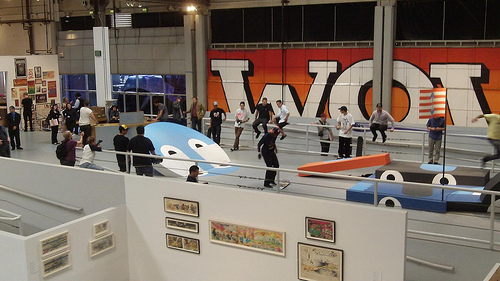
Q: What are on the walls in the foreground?
A: Framed pictures.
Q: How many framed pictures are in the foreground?
A: Ten.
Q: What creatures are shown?
A: People.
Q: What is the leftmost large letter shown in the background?
A: W.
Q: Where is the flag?
A: On the right.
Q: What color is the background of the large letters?
A: Orange.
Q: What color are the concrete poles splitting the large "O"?
A: Gray.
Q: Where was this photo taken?
A: At a museum.